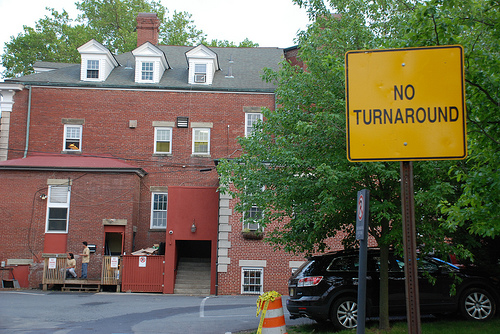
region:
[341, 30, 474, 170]
yellow sign with black letters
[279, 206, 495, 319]
black car parked under a tree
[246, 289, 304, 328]
orange and black barrel behind car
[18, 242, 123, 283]
people sitting on the patio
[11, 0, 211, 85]
trees behind the house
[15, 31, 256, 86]
three windows on top of the house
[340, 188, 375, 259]
no parking sign with red and white writing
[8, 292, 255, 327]
black pavement in front of building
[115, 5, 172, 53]
smoke stack on top of house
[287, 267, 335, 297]
tail lights on black car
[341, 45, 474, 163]
a yellow and black road sign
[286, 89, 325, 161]
the leaves of a building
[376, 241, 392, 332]
the trunk of a tree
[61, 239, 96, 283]
two people on a deck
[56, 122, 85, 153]
an open window of a building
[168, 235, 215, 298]
the door way to a building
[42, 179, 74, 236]
a window of a building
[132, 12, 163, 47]
a brick chimney on a roof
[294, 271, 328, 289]
the tail light of a car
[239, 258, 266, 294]
a window of a building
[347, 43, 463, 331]
yellow sign that says "no turnaround"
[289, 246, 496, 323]
black SUV parked in a lot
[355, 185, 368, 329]
gray no parking sign next to the vehicle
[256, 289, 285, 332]
orange and white striped cone with yellow caution tape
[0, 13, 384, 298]
red brick building in the background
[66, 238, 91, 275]
people standing on a wooden platform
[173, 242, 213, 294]
stairway entrance into the building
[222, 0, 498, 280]
large green tree next to the vehicle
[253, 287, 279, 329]
yellow caution tape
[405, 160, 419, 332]
metal post for the sign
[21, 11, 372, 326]
Picture taken outdoors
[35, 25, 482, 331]
Picture taken during the day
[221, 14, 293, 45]
It is a overcast sky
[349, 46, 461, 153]
A sign says No Turnaround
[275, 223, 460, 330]
A black suv parked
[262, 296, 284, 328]
A orange and white cone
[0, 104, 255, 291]
a large brick building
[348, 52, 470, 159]
the sign is yellow and black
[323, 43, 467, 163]
the sign is square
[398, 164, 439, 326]
the sign is on a post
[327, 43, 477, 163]
the sign is orange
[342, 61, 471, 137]
black letters on sign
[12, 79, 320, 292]
building made of brick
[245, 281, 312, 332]
cone is orange and white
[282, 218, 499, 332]
the car is black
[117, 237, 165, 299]
the dumpster is red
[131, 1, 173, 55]
chimney on the roof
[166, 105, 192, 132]
light on the building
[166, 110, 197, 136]
the light is black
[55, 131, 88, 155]
object or person sticking out of window